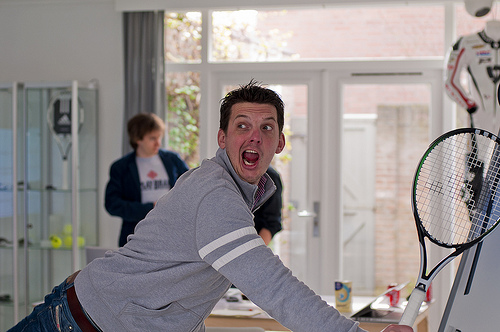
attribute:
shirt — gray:
[73, 153, 375, 328]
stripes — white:
[200, 225, 263, 265]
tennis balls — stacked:
[46, 219, 89, 247]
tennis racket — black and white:
[396, 127, 498, 327]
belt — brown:
[64, 270, 100, 329]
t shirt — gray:
[70, 148, 372, 328]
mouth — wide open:
[237, 145, 261, 170]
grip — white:
[395, 288, 425, 327]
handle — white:
[395, 284, 432, 323]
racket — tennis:
[391, 125, 484, 322]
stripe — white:
[212, 237, 266, 273]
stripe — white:
[196, 226, 255, 256]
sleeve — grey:
[194, 185, 332, 319]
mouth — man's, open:
[234, 137, 263, 171]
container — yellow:
[332, 277, 354, 320]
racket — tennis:
[41, 88, 89, 189]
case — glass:
[13, 74, 102, 298]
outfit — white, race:
[441, 29, 481, 180]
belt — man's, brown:
[60, 271, 87, 323]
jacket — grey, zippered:
[65, 148, 370, 328]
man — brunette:
[26, 80, 409, 318]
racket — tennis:
[400, 127, 484, 319]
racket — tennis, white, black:
[397, 119, 470, 316]